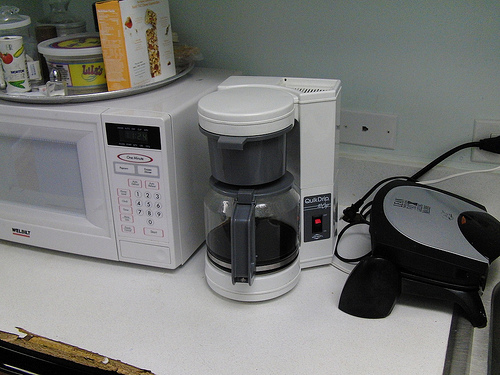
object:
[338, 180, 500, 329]
grill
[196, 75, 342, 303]
coffee maker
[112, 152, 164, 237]
button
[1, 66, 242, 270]
microwave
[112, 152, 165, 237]
buttons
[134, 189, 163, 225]
number pad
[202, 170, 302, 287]
coffee pot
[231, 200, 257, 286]
handle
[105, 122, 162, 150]
display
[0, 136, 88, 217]
window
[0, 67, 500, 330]
appliances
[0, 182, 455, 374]
counter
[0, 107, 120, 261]
door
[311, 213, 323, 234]
switch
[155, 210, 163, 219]
button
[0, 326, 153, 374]
crack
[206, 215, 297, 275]
coffee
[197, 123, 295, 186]
filter basket